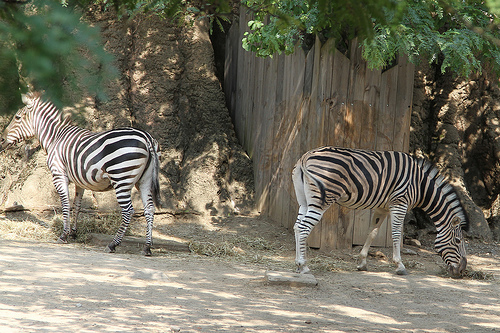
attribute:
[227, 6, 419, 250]
fence — brown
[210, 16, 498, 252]
tree — green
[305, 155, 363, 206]
stripe — black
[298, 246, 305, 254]
stripe — black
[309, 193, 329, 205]
stripe — black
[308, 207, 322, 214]
stripe — black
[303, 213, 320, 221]
stripe — black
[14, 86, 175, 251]
zebra — white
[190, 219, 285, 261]
hay — yellow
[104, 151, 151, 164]
stripe — black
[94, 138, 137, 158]
stripe — black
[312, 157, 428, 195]
stripes — black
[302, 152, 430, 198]
stripes — brown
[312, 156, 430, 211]
stripes — black